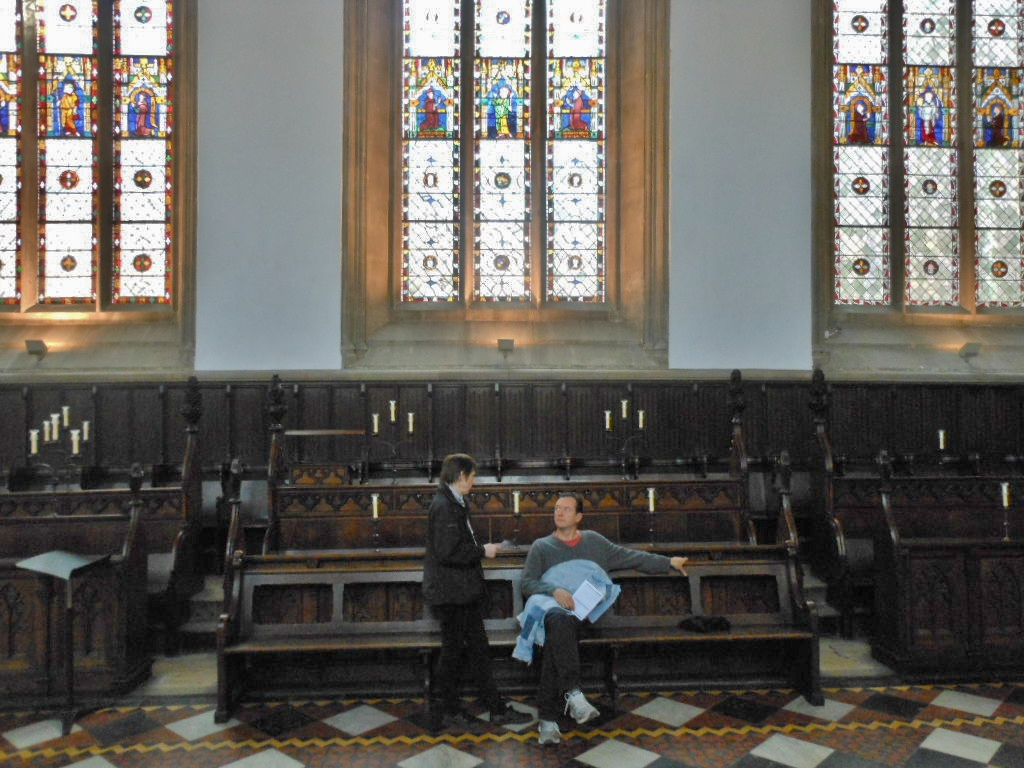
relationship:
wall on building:
[5, 5, 1012, 375] [14, 5, 1015, 762]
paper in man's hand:
[561, 569, 607, 621] [547, 586, 587, 621]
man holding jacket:
[500, 469, 710, 757] [513, 579, 581, 666]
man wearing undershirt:
[517, 478, 695, 744] [558, 526, 589, 552]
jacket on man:
[423, 485, 490, 613] [421, 450, 532, 734]